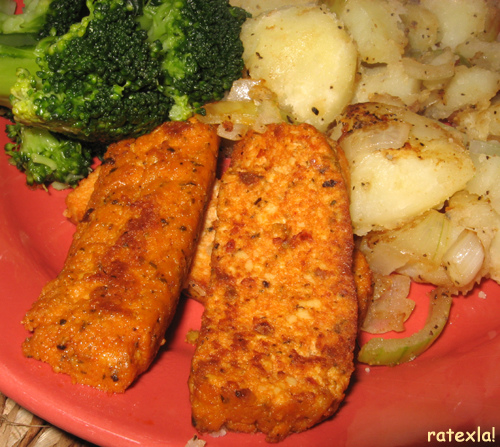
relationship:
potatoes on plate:
[346, 0, 499, 278] [355, 268, 498, 447]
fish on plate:
[193, 124, 356, 424] [355, 268, 498, 447]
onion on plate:
[363, 327, 439, 366] [355, 268, 498, 447]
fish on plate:
[37, 121, 217, 381] [355, 268, 498, 447]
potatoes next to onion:
[346, 0, 499, 278] [363, 327, 439, 366]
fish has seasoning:
[193, 124, 356, 424] [250, 233, 259, 239]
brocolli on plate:
[1, 0, 240, 138] [355, 268, 498, 447]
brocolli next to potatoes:
[1, 0, 240, 138] [346, 0, 499, 278]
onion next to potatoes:
[363, 327, 439, 366] [346, 0, 499, 278]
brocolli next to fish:
[1, 0, 240, 138] [37, 121, 217, 381]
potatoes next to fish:
[346, 0, 499, 278] [193, 124, 356, 424]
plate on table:
[355, 268, 498, 447] [1, 396, 86, 446]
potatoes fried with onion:
[346, 0, 499, 278] [363, 327, 439, 366]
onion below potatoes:
[363, 327, 439, 366] [346, 0, 499, 278]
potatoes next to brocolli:
[346, 0, 499, 278] [1, 0, 240, 138]